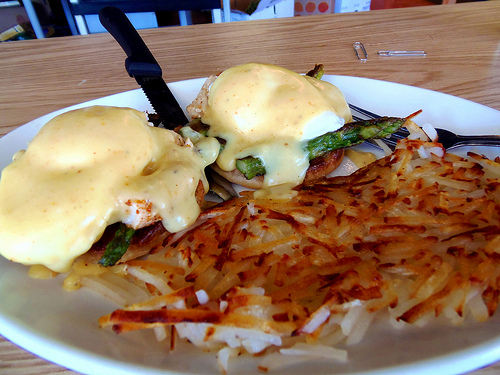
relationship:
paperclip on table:
[351, 39, 371, 59] [0, 0, 499, 372]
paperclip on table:
[377, 49, 427, 60] [0, 0, 499, 372]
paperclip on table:
[351, 34, 371, 58] [0, 0, 499, 372]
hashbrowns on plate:
[97, 134, 497, 364] [0, 72, 500, 372]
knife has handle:
[97, 4, 187, 130] [97, 1, 161, 74]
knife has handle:
[97, 4, 187, 130] [97, 5, 161, 78]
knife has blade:
[97, 4, 187, 130] [134, 70, 190, 128]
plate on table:
[0, 72, 500, 372] [0, 0, 499, 372]